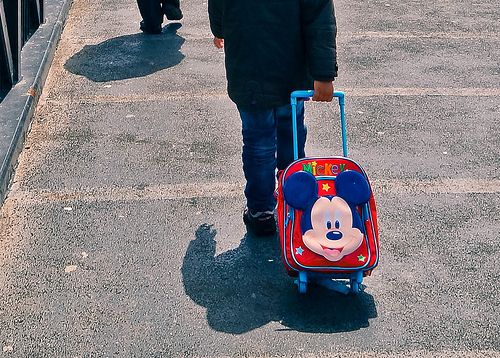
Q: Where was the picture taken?
A: It was taken at the pavement.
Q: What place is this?
A: It is a pavement.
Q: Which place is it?
A: It is a pavement.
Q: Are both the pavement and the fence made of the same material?
A: No, the pavement is made of concrete and the fence is made of metal.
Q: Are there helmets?
A: No, there are no helmets.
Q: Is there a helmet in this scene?
A: No, there are no helmets.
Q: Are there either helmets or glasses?
A: No, there are no helmets or glasses.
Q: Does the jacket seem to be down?
A: Yes, the jacket is down.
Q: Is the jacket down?
A: Yes, the jacket is down.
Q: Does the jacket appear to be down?
A: Yes, the jacket is down.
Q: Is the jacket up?
A: No, the jacket is down.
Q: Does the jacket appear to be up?
A: No, the jacket is down.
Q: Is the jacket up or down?
A: The jacket is down.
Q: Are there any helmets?
A: No, there are no helmets.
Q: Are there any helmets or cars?
A: No, there are no helmets or cars.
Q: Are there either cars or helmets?
A: No, there are no helmets or cars.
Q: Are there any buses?
A: No, there are no buses.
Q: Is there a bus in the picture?
A: No, there are no buses.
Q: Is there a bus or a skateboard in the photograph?
A: No, there are no buses or skateboards.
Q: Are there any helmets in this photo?
A: No, there are no helmets.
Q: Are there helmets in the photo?
A: No, there are no helmets.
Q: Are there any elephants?
A: No, there are no elephants.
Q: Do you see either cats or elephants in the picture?
A: No, there are no elephants or cats.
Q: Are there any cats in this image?
A: No, there are no cats.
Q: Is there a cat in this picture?
A: No, there are no cats.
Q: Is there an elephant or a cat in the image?
A: No, there are no cats or elephants.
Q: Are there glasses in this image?
A: No, there are no glasses.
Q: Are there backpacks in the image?
A: Yes, there is a backpack.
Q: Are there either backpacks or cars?
A: Yes, there is a backpack.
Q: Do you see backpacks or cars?
A: Yes, there is a backpack.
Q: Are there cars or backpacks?
A: Yes, there is a backpack.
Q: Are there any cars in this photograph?
A: No, there are no cars.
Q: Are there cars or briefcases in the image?
A: No, there are no cars or briefcases.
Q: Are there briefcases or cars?
A: No, there are no cars or briefcases.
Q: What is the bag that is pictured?
A: The bag is a backpack.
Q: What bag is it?
A: The bag is a backpack.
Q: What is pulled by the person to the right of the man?
A: The backpack is pulled by the person.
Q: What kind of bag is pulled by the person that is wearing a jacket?
A: The bag is a backpack.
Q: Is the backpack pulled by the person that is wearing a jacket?
A: Yes, the backpack is pulled by the person.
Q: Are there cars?
A: No, there are no cars.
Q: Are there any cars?
A: No, there are no cars.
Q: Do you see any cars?
A: No, there are no cars.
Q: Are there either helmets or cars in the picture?
A: No, there are no cars or helmets.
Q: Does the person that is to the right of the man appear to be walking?
A: Yes, the person is walking.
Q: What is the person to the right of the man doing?
A: The person is walking.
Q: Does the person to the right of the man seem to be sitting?
A: No, the person is walking.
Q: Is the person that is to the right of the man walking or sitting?
A: The person is walking.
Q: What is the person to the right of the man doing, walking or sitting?
A: The person is walking.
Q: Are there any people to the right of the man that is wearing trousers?
A: Yes, there is a person to the right of the man.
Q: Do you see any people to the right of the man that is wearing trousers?
A: Yes, there is a person to the right of the man.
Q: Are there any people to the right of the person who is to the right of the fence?
A: Yes, there is a person to the right of the man.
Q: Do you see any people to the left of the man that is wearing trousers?
A: No, the person is to the right of the man.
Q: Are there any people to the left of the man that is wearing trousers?
A: No, the person is to the right of the man.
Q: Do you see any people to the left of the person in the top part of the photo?
A: No, the person is to the right of the man.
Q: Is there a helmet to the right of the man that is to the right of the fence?
A: No, there is a person to the right of the man.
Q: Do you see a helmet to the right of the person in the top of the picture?
A: No, there is a person to the right of the man.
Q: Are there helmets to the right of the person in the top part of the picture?
A: No, there is a person to the right of the man.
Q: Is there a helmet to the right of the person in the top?
A: No, there is a person to the right of the man.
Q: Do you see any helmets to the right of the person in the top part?
A: No, there is a person to the right of the man.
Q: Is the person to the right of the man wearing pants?
A: Yes, the person is wearing pants.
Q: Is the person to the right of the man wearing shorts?
A: No, the person is wearing pants.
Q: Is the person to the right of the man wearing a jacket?
A: Yes, the person is wearing a jacket.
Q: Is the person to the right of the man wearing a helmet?
A: No, the person is wearing a jacket.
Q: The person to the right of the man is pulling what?
A: The person is pulling the backpack.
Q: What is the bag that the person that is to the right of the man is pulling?
A: The bag is a backpack.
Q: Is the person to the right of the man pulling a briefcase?
A: No, the person is pulling the backpack.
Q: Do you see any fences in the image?
A: Yes, there is a fence.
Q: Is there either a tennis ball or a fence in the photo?
A: Yes, there is a fence.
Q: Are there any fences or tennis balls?
A: Yes, there is a fence.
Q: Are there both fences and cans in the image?
A: No, there is a fence but no cans.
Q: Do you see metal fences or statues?
A: Yes, there is a metal fence.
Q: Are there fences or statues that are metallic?
A: Yes, the fence is metallic.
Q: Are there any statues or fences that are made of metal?
A: Yes, the fence is made of metal.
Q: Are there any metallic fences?
A: Yes, there is a metal fence.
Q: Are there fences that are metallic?
A: Yes, there is a fence that is metallic.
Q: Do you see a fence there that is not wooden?
A: Yes, there is a metallic fence.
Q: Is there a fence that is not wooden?
A: Yes, there is a metallic fence.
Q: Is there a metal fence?
A: Yes, there is a fence that is made of metal.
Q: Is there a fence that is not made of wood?
A: Yes, there is a fence that is made of metal.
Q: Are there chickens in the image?
A: No, there are no chickens.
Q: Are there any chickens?
A: No, there are no chickens.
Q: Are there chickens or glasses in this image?
A: No, there are no chickens or glasses.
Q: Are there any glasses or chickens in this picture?
A: No, there are no chickens or glasses.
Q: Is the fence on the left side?
A: Yes, the fence is on the left of the image.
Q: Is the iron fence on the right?
A: No, the fence is on the left of the image.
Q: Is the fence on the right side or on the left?
A: The fence is on the left of the image.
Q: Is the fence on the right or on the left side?
A: The fence is on the left of the image.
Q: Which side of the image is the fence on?
A: The fence is on the left of the image.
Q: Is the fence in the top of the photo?
A: Yes, the fence is in the top of the image.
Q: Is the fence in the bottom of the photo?
A: No, the fence is in the top of the image.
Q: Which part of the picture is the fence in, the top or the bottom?
A: The fence is in the top of the image.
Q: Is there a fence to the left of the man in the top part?
A: Yes, there is a fence to the left of the man.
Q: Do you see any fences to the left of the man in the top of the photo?
A: Yes, there is a fence to the left of the man.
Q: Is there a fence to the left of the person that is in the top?
A: Yes, there is a fence to the left of the man.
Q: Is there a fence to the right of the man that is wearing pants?
A: No, the fence is to the left of the man.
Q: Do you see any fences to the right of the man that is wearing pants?
A: No, the fence is to the left of the man.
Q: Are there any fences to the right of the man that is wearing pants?
A: No, the fence is to the left of the man.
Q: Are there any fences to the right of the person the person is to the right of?
A: No, the fence is to the left of the man.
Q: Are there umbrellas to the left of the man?
A: No, there is a fence to the left of the man.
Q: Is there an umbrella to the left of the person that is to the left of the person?
A: No, there is a fence to the left of the man.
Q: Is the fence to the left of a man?
A: Yes, the fence is to the left of a man.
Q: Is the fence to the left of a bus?
A: No, the fence is to the left of a man.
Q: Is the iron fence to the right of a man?
A: No, the fence is to the left of a man.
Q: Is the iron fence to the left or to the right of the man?
A: The fence is to the left of the man.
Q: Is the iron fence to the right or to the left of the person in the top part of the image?
A: The fence is to the left of the man.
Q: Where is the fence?
A: The fence is on the pavement.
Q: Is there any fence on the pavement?
A: Yes, there is a fence on the pavement.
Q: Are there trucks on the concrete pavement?
A: No, there is a fence on the pavement.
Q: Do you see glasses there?
A: No, there are no glasses.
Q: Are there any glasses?
A: No, there are no glasses.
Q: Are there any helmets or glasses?
A: No, there are no glasses or helmets.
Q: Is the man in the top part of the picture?
A: Yes, the man is in the top of the image.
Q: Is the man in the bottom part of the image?
A: No, the man is in the top of the image.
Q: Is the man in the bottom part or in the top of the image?
A: The man is in the top of the image.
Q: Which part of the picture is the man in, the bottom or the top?
A: The man is in the top of the image.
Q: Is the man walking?
A: Yes, the man is walking.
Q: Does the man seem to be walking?
A: Yes, the man is walking.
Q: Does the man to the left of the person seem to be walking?
A: Yes, the man is walking.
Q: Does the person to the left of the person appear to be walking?
A: Yes, the man is walking.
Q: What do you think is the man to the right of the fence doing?
A: The man is walking.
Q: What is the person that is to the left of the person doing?
A: The man is walking.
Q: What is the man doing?
A: The man is walking.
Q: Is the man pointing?
A: No, the man is walking.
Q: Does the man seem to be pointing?
A: No, the man is walking.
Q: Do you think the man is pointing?
A: No, the man is walking.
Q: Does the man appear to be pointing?
A: No, the man is walking.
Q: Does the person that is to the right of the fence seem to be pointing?
A: No, the man is walking.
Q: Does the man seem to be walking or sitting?
A: The man is walking.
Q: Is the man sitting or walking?
A: The man is walking.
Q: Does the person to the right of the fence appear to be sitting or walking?
A: The man is walking.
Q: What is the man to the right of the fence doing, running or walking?
A: The man is walking.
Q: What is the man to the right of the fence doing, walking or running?
A: The man is walking.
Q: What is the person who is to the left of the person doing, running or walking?
A: The man is walking.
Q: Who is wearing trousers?
A: The man is wearing trousers.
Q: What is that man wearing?
A: The man is wearing pants.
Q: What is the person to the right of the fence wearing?
A: The man is wearing pants.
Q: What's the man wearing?
A: The man is wearing pants.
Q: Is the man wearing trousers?
A: Yes, the man is wearing trousers.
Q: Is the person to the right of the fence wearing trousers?
A: Yes, the man is wearing trousers.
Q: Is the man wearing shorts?
A: No, the man is wearing trousers.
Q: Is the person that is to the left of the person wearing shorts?
A: No, the man is wearing trousers.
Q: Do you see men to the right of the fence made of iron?
A: Yes, there is a man to the right of the fence.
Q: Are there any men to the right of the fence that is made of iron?
A: Yes, there is a man to the right of the fence.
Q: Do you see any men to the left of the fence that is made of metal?
A: No, the man is to the right of the fence.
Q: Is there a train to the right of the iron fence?
A: No, there is a man to the right of the fence.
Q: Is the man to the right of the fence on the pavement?
A: Yes, the man is to the right of the fence.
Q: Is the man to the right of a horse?
A: No, the man is to the right of the fence.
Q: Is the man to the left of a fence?
A: No, the man is to the right of a fence.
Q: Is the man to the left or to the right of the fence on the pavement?
A: The man is to the right of the fence.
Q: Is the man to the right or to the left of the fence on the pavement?
A: The man is to the right of the fence.